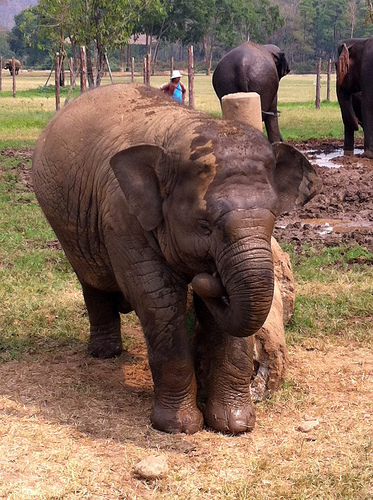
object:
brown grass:
[0, 334, 373, 498]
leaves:
[148, 4, 193, 20]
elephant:
[32, 83, 322, 436]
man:
[159, 70, 186, 105]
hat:
[170, 70, 182, 83]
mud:
[272, 135, 373, 271]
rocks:
[134, 455, 167, 479]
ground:
[3, 247, 371, 499]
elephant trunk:
[192, 223, 274, 338]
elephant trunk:
[336, 85, 358, 130]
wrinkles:
[223, 235, 273, 330]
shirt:
[172, 83, 182, 103]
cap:
[170, 69, 182, 79]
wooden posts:
[55, 56, 59, 112]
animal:
[212, 42, 290, 143]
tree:
[199, 0, 230, 75]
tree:
[213, 0, 286, 46]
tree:
[131, 0, 212, 63]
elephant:
[335, 38, 373, 160]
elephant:
[4, 59, 21, 76]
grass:
[0, 67, 373, 500]